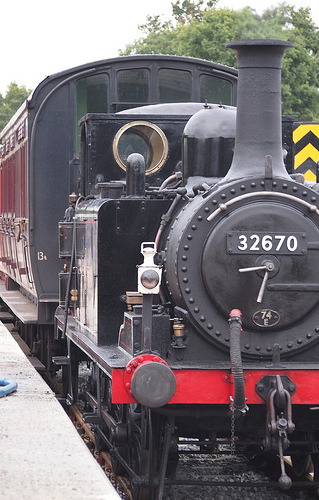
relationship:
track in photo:
[49, 356, 316, 500] [0, 0, 317, 498]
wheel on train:
[123, 403, 155, 499] [2, 38, 318, 498]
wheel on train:
[102, 377, 127, 474] [2, 38, 318, 498]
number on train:
[287, 233, 298, 255] [2, 38, 318, 498]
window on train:
[71, 70, 111, 155] [2, 38, 318, 498]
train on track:
[2, 38, 318, 498] [45, 356, 316, 497]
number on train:
[232, 230, 302, 254] [2, 38, 318, 498]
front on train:
[112, 37, 318, 403] [2, 38, 318, 498]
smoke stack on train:
[223, 32, 295, 188] [2, 38, 318, 498]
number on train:
[234, 231, 249, 253] [2, 38, 318, 498]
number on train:
[250, 232, 260, 251] [2, 38, 318, 498]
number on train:
[261, 233, 272, 250] [2, 38, 318, 498]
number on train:
[274, 233, 286, 253] [2, 38, 318, 498]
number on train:
[237, 233, 298, 254] [98, 112, 205, 281]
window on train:
[202, 75, 232, 100] [17, 21, 316, 325]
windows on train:
[89, 72, 246, 138] [7, 62, 317, 391]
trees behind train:
[1, 84, 22, 106] [47, 71, 244, 325]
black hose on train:
[226, 339, 273, 349] [6, 131, 160, 262]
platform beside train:
[10, 391, 65, 497] [0, 117, 303, 414]